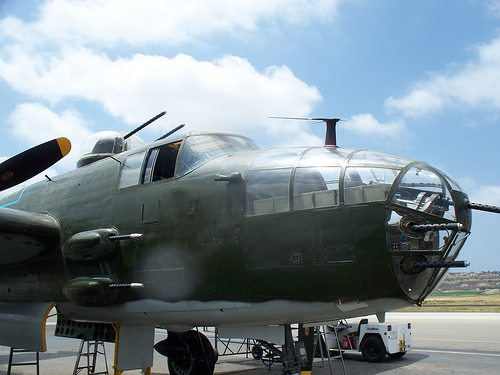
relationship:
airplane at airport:
[3, 109, 495, 375] [0, 273, 493, 373]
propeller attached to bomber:
[1, 127, 72, 192] [33, 111, 469, 372]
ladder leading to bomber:
[68, 321, 111, 373] [0, 109, 499, 374]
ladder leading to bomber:
[6, 347, 43, 373] [0, 109, 499, 374]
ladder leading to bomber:
[321, 322, 347, 372] [0, 109, 499, 374]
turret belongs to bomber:
[76, 127, 140, 162] [71, 105, 189, 179]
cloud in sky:
[1, 0, 336, 158] [4, 2, 499, 274]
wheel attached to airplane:
[166, 330, 215, 372] [3, 109, 495, 375]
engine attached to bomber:
[88, 276, 117, 311] [33, 111, 469, 372]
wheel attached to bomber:
[166, 330, 215, 375] [37, 134, 467, 372]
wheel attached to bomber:
[166, 330, 215, 375] [33, 111, 469, 372]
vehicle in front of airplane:
[322, 319, 414, 363] [3, 109, 495, 375]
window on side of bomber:
[127, 142, 178, 179] [33, 111, 469, 372]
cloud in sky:
[346, 106, 403, 153] [4, 2, 499, 274]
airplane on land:
[3, 109, 495, 375] [264, 313, 500, 360]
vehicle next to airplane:
[332, 318, 415, 360] [3, 109, 495, 375]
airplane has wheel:
[3, 109, 495, 375] [156, 330, 221, 373]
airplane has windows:
[3, 109, 495, 375] [117, 142, 189, 192]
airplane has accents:
[3, 109, 495, 375] [36, 130, 135, 372]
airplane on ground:
[3, 109, 495, 375] [1, 305, 498, 374]